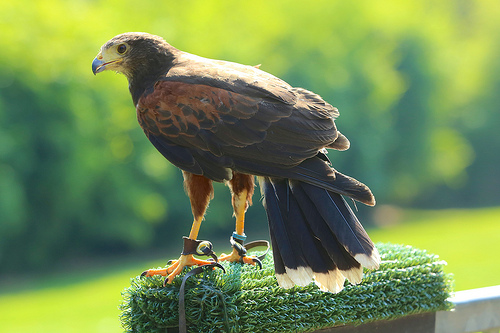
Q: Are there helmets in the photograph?
A: No, there are no helmets.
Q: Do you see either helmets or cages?
A: No, there are no helmets or cages.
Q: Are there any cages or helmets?
A: No, there are no helmets or cages.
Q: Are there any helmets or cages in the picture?
A: No, there are no helmets or cages.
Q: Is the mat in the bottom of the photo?
A: Yes, the mat is in the bottom of the image.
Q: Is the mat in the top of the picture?
A: No, the mat is in the bottom of the image.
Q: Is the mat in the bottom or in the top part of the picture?
A: The mat is in the bottom of the image.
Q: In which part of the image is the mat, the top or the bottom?
A: The mat is in the bottom of the image.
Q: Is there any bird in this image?
A: Yes, there is a bird.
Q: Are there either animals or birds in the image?
A: Yes, there is a bird.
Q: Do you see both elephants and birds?
A: No, there is a bird but no elephants.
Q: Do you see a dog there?
A: No, there are no dogs.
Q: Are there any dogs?
A: No, there are no dogs.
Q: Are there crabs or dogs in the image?
A: No, there are no dogs or crabs.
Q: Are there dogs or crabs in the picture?
A: No, there are no dogs or crabs.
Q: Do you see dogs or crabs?
A: No, there are no dogs or crabs.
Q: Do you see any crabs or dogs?
A: No, there are no dogs or crabs.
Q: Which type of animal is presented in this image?
A: The animal is a bird.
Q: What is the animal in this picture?
A: The animal is a bird.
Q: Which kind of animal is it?
A: The animal is a bird.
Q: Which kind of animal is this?
A: This is a bird.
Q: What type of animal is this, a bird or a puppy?
A: This is a bird.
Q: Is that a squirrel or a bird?
A: That is a bird.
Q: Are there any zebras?
A: No, there are no zebras.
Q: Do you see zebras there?
A: No, there are no zebras.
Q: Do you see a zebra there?
A: No, there are no zebras.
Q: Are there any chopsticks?
A: No, there are no chopsticks.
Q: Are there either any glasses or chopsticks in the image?
A: No, there are no chopsticks or glasses.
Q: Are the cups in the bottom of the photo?
A: Yes, the cups are in the bottom of the image.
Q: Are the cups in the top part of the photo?
A: No, the cups are in the bottom of the image.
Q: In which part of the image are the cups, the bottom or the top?
A: The cups are in the bottom of the image.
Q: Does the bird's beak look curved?
A: Yes, the beak is curved.